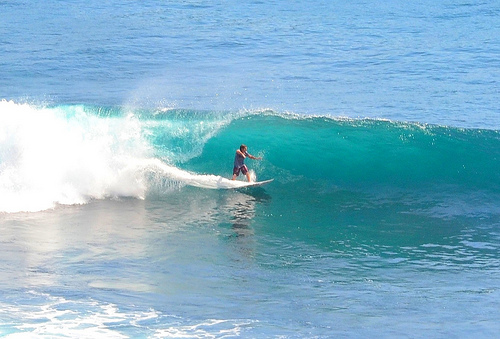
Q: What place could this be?
A: It is an ocean.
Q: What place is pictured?
A: It is an ocean.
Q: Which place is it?
A: It is an ocean.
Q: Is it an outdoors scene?
A: Yes, it is outdoors.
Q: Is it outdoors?
A: Yes, it is outdoors.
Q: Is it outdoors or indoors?
A: It is outdoors.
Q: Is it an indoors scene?
A: No, it is outdoors.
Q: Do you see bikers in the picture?
A: No, there are no bikers.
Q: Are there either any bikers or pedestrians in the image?
A: No, there are no bikers or pedestrians.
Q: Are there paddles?
A: No, there are no paddles.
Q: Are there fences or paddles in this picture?
A: No, there are no paddles or fences.